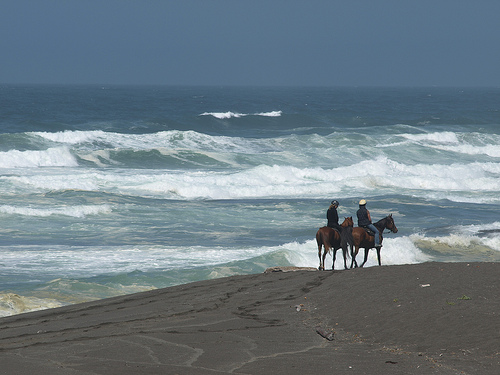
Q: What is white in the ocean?
A: The waves are white in the ocean.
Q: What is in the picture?
A: A pair of brown horses.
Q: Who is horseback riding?
A: Some people.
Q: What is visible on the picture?
A: A pair of horses on the beach.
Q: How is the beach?
A: Dark and sandy.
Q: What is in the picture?
A: A few ocean waves.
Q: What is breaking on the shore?
A: Waves.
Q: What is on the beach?
A: Sand.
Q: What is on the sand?
A: Sea weed.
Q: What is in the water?
A: Large white capped waves.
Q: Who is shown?
A: Women.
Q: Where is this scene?
A: The beach.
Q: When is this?
A: During the day.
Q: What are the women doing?
A: Horseback riding.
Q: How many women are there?
A: Two.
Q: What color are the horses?
A: Brown.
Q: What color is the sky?
A: Blue.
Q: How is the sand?
A: Wet.